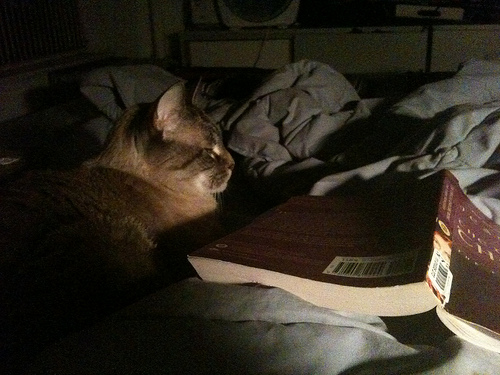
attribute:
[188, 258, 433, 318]
paper — white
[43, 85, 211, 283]
cat — sleeping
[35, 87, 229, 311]
cat — sleeping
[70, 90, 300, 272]
cat — tabby, laying down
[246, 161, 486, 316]
book — open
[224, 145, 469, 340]
book — open, softback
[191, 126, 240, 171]
eye — closed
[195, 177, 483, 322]
book — brown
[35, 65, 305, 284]
cat — asleep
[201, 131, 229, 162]
eye — closed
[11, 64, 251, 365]
cat — sleeping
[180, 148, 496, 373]
book — open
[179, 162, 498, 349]
book — laying down, turned over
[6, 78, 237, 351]
cat — brown, laying down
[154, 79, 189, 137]
ear — brown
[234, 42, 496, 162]
blanket — grey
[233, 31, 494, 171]
blanket — wrinkled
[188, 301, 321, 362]
cover — top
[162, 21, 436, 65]
shelf — top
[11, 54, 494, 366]
cover — green/gray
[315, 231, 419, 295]
label — white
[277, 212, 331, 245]
lettering — white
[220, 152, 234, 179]
nose — brown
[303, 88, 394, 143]
blanket — grey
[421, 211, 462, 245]
sticker — yellow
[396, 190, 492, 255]
lettering — yellow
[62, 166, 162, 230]
stripes — yellowish, brown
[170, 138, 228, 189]
stripe — brown, dark